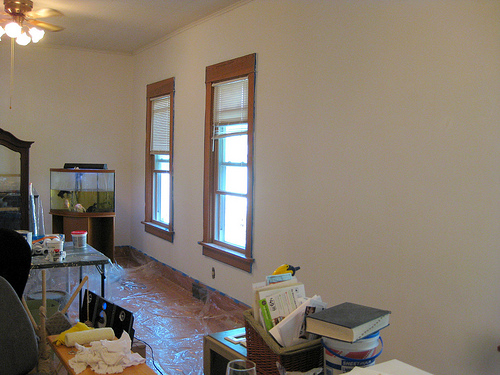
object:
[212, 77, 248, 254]
double/hung window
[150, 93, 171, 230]
double/hung window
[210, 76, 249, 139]
white/venetian blind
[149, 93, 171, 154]
white/venetian blind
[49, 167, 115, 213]
large/fish aquarium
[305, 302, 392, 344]
black/hardback book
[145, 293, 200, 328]
clear/plastic tarp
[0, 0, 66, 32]
ceiling fan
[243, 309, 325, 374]
basket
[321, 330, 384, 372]
bucket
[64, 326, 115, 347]
yellow/paint roller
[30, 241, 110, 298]
dark table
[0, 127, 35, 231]
framed mirror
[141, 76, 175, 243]
large/brown window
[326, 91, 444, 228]
part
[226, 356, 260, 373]
part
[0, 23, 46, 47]
four lights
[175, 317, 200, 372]
small patch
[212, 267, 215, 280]
outlet plug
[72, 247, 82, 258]
small part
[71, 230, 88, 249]
plastic container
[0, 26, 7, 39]
light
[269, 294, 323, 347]
papers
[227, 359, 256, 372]
top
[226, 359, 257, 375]
glass